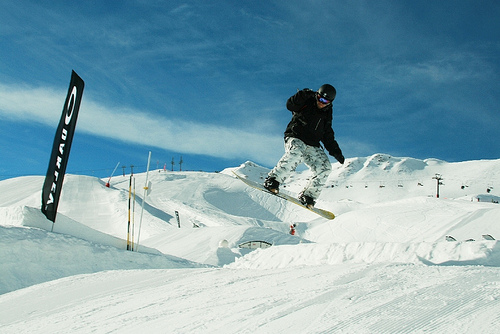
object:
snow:
[6, 248, 187, 301]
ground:
[293, 221, 339, 330]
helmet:
[317, 83, 336, 102]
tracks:
[90, 266, 500, 332]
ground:
[2, 192, 132, 331]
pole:
[131, 177, 138, 250]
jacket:
[284, 87, 342, 155]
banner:
[40, 69, 85, 223]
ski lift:
[397, 179, 404, 187]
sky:
[0, 0, 500, 154]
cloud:
[7, 80, 271, 167]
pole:
[134, 150, 152, 251]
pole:
[126, 176, 132, 251]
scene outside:
[0, 0, 499, 286]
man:
[264, 83, 344, 209]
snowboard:
[230, 169, 335, 220]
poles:
[105, 161, 120, 187]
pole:
[178, 154, 184, 171]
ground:
[397, 223, 500, 331]